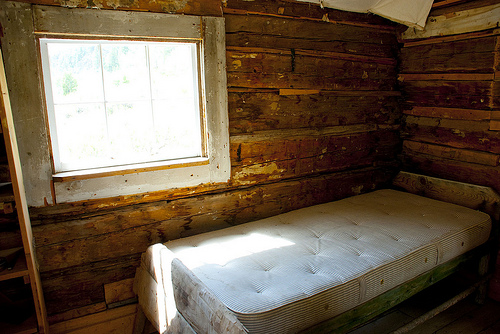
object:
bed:
[134, 169, 499, 333]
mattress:
[161, 188, 493, 334]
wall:
[2, 1, 396, 324]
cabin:
[2, 1, 499, 332]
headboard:
[392, 168, 499, 213]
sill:
[51, 156, 210, 205]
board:
[106, 277, 140, 307]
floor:
[5, 289, 499, 334]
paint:
[20, 110, 41, 164]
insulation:
[312, 0, 432, 27]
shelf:
[1, 119, 56, 332]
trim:
[0, 2, 235, 208]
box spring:
[300, 254, 467, 333]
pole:
[474, 255, 490, 305]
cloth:
[132, 245, 179, 334]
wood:
[209, 124, 229, 149]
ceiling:
[183, 2, 499, 30]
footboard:
[140, 241, 250, 334]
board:
[305, 264, 480, 333]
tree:
[92, 40, 115, 128]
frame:
[2, 1, 231, 209]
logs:
[232, 95, 327, 128]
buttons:
[264, 269, 269, 273]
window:
[2, 4, 238, 210]